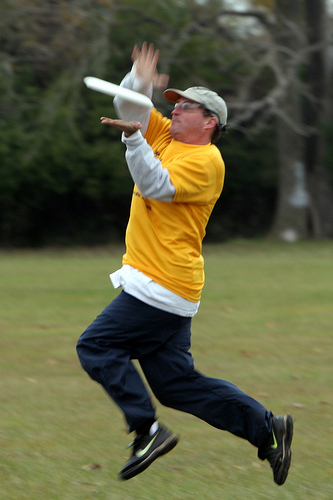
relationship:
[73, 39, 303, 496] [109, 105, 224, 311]
man wearing t shirt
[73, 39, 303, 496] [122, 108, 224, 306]
man wearing shirt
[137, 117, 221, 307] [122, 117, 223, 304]
t-shirt over t-shirt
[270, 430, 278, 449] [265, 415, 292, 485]
stripe on sneaker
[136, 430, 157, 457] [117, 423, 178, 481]
stripe on sneaker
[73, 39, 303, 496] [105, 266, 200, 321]
man wearing teeshirt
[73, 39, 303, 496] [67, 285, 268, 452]
man wearing pants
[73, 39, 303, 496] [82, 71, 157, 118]
man catching frisbee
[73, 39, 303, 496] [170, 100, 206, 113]
man wearing eyeglasses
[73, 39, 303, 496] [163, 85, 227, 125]
man wearing hat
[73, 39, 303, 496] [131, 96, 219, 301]
man wearing shirt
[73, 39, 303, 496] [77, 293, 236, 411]
man wearing pants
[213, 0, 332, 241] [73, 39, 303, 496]
tree behind man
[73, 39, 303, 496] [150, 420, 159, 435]
man wears socks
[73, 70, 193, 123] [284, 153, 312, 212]
frisbee has target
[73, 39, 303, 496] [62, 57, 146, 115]
man holding frisbee